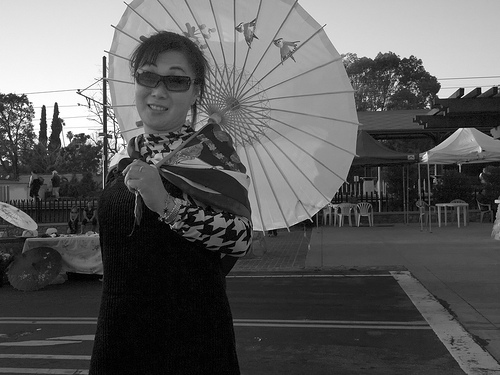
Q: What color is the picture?
A: Black and white.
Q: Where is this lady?
A: Outside on the streets.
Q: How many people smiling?
A: One.